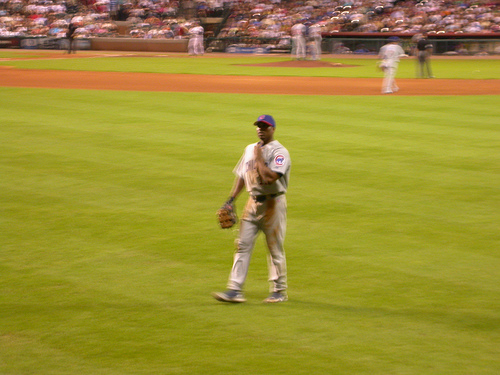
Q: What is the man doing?
A: Playing baseball.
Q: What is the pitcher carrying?
A: Mitt.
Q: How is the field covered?
A: With grass.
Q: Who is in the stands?
A: Spectators.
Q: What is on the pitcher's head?
A: A baseball cap.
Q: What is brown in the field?
A: Baseball mounds.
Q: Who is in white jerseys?
A: Players.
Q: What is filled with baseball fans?
A: A grandstand.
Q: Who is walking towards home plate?
A: A baseball player.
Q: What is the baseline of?
A: A baseball field.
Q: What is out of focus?
A: Baseball players.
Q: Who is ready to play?
A: The baseball player.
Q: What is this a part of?
A: Baseball field.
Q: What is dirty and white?
A: Baseball pants.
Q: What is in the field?
A: Grass.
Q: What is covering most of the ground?
A: Grass.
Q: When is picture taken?
A: During a baseball game.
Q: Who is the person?
A: A player.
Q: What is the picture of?
A: Baseball game.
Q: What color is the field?
A: Green.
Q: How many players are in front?
A: One.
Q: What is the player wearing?
A: A glove.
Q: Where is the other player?
A: Background.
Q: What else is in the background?
A: Fans.